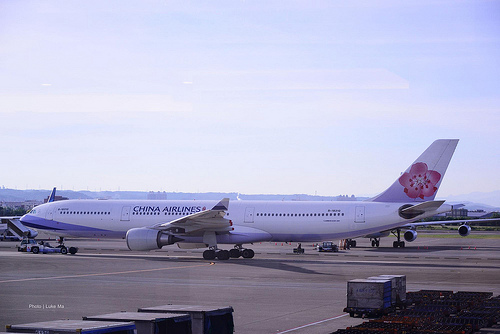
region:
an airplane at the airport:
[14, 141, 474, 250]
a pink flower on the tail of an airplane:
[397, 160, 449, 200]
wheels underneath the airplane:
[12, 231, 386, 275]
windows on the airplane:
[52, 208, 356, 219]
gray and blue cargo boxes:
[343, 273, 418, 317]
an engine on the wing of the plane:
[116, 224, 183, 250]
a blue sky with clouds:
[3, 5, 498, 193]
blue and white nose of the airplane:
[15, 195, 77, 240]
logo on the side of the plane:
[127, 203, 209, 218]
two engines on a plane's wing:
[402, 218, 479, 250]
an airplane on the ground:
[10, 61, 385, 330]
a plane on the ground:
[7, 53, 432, 329]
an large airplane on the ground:
[22, 77, 492, 307]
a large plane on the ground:
[28, 83, 373, 333]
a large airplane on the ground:
[22, 97, 482, 330]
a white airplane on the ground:
[23, 61, 483, 303]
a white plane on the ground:
[26, 46, 485, 316]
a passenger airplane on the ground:
[33, 36, 499, 296]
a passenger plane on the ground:
[22, 71, 490, 324]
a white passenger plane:
[3, 66, 494, 318]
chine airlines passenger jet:
[25, 126, 475, 261]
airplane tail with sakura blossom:
[394, 135, 460, 207]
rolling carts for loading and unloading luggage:
[348, 272, 410, 320]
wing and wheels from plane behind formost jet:
[343, 219, 492, 248]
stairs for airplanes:
[4, 219, 74, 256]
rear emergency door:
[244, 207, 259, 224]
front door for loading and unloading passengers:
[116, 204, 141, 222]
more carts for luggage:
[7, 304, 244, 328]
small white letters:
[22, 302, 68, 309]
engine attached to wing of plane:
[124, 231, 179, 258]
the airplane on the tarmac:
[20, 137, 464, 261]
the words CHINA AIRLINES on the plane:
[130, 202, 201, 213]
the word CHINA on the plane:
[131, 203, 163, 212]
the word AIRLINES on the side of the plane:
[161, 204, 203, 213]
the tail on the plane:
[372, 137, 460, 197]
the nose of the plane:
[16, 208, 31, 225]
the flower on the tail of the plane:
[398, 162, 440, 199]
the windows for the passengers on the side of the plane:
[58, 209, 350, 218]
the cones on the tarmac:
[412, 243, 480, 250]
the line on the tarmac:
[8, 255, 204, 296]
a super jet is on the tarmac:
[15, 136, 460, 262]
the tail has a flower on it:
[366, 135, 462, 205]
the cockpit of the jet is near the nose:
[19, 196, 57, 234]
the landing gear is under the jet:
[54, 235, 256, 262]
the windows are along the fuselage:
[54, 204, 345, 223]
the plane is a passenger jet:
[23, 137, 460, 252]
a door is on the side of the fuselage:
[116, 200, 134, 227]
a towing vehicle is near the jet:
[21, 231, 76, 261]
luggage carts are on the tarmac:
[340, 265, 404, 315]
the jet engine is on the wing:
[123, 199, 235, 253]